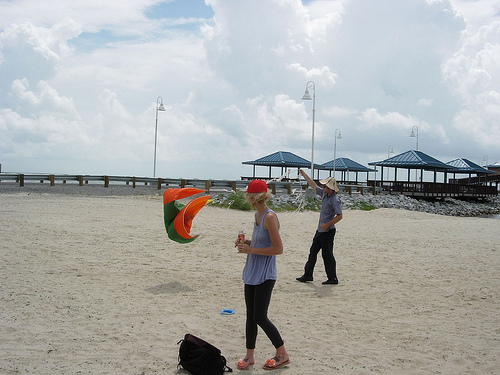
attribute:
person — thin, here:
[233, 177, 294, 370]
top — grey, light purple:
[241, 210, 281, 284]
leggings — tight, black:
[243, 279, 285, 350]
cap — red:
[240, 178, 269, 194]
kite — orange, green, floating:
[162, 185, 212, 244]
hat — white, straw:
[317, 175, 341, 192]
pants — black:
[302, 227, 336, 280]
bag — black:
[177, 332, 233, 374]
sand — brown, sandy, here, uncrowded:
[1, 194, 497, 375]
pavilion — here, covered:
[367, 148, 461, 205]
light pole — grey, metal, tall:
[302, 79, 316, 202]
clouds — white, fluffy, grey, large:
[2, 0, 500, 170]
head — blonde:
[245, 182, 273, 205]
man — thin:
[296, 166, 344, 286]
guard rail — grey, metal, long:
[0, 174, 390, 194]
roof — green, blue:
[368, 150, 461, 170]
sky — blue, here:
[4, 2, 493, 174]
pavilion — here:
[241, 150, 325, 192]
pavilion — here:
[321, 157, 378, 193]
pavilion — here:
[436, 158, 494, 189]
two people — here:
[235, 168, 343, 371]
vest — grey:
[317, 193, 335, 233]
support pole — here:
[251, 166, 257, 179]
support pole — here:
[379, 166, 384, 182]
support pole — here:
[433, 169, 438, 182]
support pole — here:
[268, 165, 272, 178]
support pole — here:
[393, 167, 398, 182]